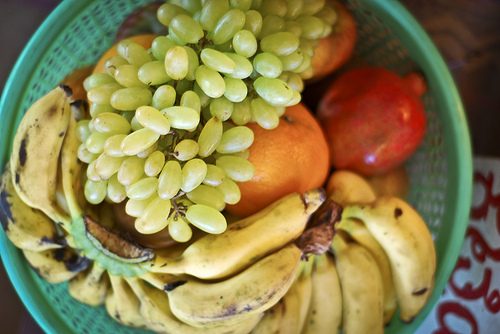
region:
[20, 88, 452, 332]
there are two bunches of bananas in the bowl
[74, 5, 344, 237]
a bunch of grapes is in the bowl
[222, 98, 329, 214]
an orange is under the grapes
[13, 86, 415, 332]
one bunch of bananas is on top of the other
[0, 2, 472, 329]
the bowl is full of different fruit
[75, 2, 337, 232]
the grapes are green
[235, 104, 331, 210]
the orange is next to both bunches of bananas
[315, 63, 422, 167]
a pomegranate is in the bowl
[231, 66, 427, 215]
the pomegranate is next to the orange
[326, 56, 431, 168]
the pomegranate is red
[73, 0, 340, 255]
fresh green grapes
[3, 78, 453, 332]
bunch of yellow and black bananas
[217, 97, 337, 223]
round orange in green basket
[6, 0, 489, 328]
green plastic basket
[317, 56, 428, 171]
red pomagrante in green basket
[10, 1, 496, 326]
outdoor picnic sunny day scene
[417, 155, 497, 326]
white paper with red lettering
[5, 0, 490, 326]
basket with a variety of fruit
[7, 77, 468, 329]
bunches of overripe bananas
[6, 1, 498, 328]
green plastic bowl with bananas and grapes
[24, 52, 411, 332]
the fruits in a basket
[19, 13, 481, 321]
the basket is green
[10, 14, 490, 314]
the basket is circle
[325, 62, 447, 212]
the apple is red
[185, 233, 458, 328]
the bananas are yellow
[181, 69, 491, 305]
the orange is in the basket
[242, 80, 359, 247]
the orange is round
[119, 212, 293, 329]
the bananas are small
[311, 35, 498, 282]
the apple is in the basket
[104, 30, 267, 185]
bunch of green grapes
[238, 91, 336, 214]
orange in middle of basket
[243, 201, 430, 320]
ripe banana bunch in green basket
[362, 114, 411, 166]
light reflection on fuit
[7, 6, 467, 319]
green basket full of fruit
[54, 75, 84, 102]
black tip of banana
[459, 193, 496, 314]
red designs on white paper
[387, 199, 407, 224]
dark discoloration on banana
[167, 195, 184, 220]
stem on green grapes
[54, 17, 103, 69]
holes in side of basket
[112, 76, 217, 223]
a bunch of green grapes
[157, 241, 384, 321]
ripe yellow bananas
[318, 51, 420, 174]
a bright red pomegrante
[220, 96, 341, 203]
an orange and green grapes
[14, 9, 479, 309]
fruit in a green strainer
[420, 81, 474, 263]
the rim of a green plastic strainer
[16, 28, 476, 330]
a basket of fruit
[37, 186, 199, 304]
a green banana stem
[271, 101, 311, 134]
the stem of an orange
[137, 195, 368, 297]
green grapes and bananas